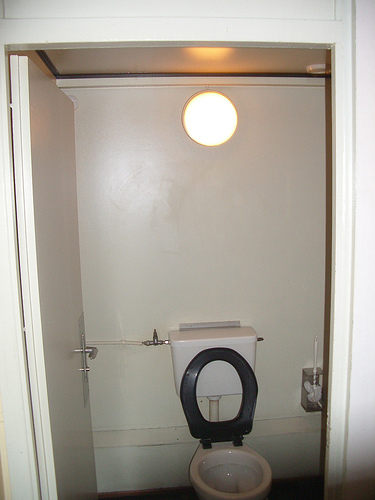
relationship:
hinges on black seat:
[198, 436, 249, 448] [180, 345, 260, 449]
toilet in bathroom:
[163, 321, 275, 494] [6, 46, 332, 498]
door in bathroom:
[9, 53, 103, 494] [76, 80, 328, 497]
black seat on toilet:
[177, 348, 217, 429] [189, 445, 278, 497]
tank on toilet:
[167, 320, 261, 399] [163, 321, 275, 494]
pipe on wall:
[88, 335, 161, 351] [79, 225, 166, 336]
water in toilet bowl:
[216, 470, 247, 496] [186, 437, 282, 497]